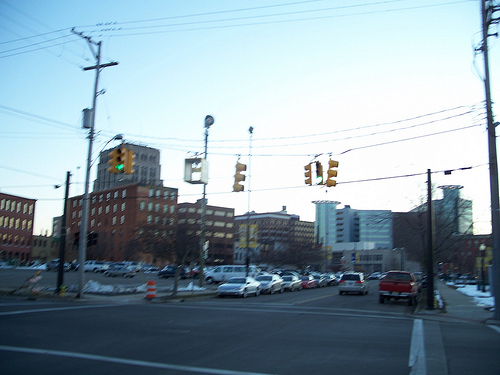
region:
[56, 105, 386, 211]
traffic lights hanging from a wire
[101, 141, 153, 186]
One traffic light with green lit up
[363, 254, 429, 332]
a red truck parked at the curb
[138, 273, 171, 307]
a green and white construction barrel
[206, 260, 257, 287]
a large white passenger van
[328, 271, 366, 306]
a silver car driving down the road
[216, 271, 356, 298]
a line of parked cars on the street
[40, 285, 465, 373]
white lines on the road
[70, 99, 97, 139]
an electrical box on a telephone pole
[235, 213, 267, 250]
a yellow sign on a pole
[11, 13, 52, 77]
white clouds against blue sky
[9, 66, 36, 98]
white clouds against blue sky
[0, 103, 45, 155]
white clouds against blue sky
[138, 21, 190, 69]
white clouds against blue sky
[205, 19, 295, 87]
white clouds against blue sky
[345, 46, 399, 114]
white clouds against blue sky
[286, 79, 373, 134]
white clouds against blue sky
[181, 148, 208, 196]
light signal hanging from wire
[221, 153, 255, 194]
light signal hanging from wire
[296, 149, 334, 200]
light signal hanging from wire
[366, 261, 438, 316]
the truck is red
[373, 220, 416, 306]
the truck is red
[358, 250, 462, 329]
the truck is red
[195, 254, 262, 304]
the van is white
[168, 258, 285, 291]
the van is white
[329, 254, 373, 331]
Car driving on road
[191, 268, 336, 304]
Cars parked along sidewalk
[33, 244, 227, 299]
Cars parked in a parking lot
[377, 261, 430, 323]
Red truck parked along sidewalk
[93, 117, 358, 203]
Traffic lights above street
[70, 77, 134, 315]
Utility pole along sidewalk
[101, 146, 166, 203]
Green light above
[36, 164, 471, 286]
Buildings beyond the street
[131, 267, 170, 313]
Orange and white traffic cone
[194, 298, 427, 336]
White lines in road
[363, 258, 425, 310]
A red truck parked on side of road.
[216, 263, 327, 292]
Cars parked on side of road.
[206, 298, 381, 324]
White lines in the road.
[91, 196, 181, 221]
Windows on the building.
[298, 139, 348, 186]
Traffic signals hanging from wire.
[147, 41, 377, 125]
The sky is clear.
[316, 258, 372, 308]
A car driving on road.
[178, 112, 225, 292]
Street light pole on sidewalk.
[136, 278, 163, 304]
Orange and white barrier on sidewalk.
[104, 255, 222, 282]
Cars parked in parking lot.